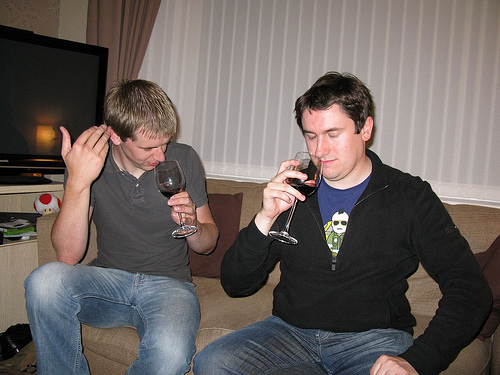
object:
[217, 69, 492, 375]
man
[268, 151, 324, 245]
wine glass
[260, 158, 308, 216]
hand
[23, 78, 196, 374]
man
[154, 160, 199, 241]
wine glass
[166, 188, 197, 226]
hand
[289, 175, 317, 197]
wine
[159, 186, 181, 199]
wine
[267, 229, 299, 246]
base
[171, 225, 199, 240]
base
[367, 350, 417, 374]
hand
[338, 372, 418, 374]
knee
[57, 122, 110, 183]
hand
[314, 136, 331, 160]
nose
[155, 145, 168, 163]
nose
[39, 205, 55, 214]
head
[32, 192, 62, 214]
mushroom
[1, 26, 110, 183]
television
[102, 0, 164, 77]
curtain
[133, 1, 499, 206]
window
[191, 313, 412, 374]
jeans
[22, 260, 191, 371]
jeans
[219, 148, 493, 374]
fleece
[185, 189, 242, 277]
pillow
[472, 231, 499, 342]
pillow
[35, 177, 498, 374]
couch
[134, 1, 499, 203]
blinds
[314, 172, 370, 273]
shirt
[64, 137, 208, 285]
shirt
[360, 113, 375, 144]
left ear